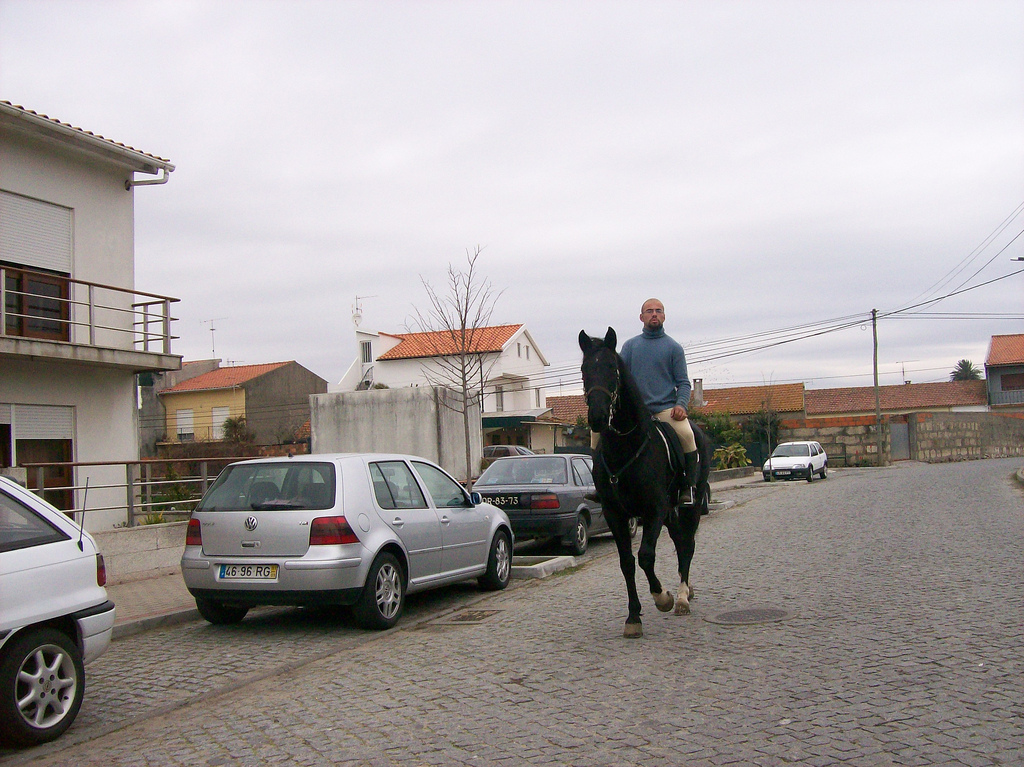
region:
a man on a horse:
[546, 241, 758, 671]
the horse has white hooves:
[591, 572, 721, 665]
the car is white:
[748, 432, 837, 506]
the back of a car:
[15, 443, 130, 763]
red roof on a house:
[360, 315, 544, 364]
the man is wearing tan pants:
[568, 268, 717, 645]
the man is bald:
[635, 285, 689, 336]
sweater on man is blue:
[622, 329, 702, 422]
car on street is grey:
[175, 449, 511, 614]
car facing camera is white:
[769, 434, 834, 489]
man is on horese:
[564, 295, 760, 646]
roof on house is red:
[374, 319, 558, 368]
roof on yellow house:
[194, 360, 296, 399]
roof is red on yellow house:
[192, 349, 291, 422]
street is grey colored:
[782, 494, 1010, 741]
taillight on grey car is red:
[308, 515, 385, 572]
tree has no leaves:
[415, 279, 527, 460]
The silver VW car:
[174, 433, 536, 639]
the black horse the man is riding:
[579, 313, 741, 664]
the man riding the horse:
[617, 288, 735, 507]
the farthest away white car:
[762, 420, 849, 510]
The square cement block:
[308, 379, 498, 507]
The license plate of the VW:
[215, 556, 301, 601]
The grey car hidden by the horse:
[454, 440, 628, 573]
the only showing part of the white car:
[2, 464, 158, 744]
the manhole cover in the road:
[697, 590, 805, 657]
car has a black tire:
[193, 598, 255, 625]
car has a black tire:
[348, 556, 409, 632]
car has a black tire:
[478, 534, 516, 588]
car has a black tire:
[0, 630, 84, 742]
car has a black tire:
[564, 516, 590, 558]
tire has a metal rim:
[10, 646, 80, 732]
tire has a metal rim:
[373, 563, 406, 618]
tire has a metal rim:
[491, 538, 515, 583]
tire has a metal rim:
[576, 523, 589, 547]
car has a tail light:
[310, 512, 356, 545]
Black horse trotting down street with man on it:
[579, 326, 663, 644]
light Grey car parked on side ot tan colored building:
[191, 450, 485, 571]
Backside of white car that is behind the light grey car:
[0, 473, 111, 709]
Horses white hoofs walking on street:
[656, 574, 695, 613]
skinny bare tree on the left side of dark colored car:
[405, 251, 482, 448]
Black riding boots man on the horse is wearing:
[689, 445, 700, 509]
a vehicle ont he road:
[216, 394, 438, 565]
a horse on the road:
[537, 366, 779, 619]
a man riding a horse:
[522, 310, 703, 582]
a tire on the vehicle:
[333, 547, 406, 614]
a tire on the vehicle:
[6, 632, 77, 697]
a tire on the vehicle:
[210, 591, 234, 617]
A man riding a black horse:
[560, 285, 732, 653]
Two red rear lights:
[166, 500, 367, 558]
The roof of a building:
[365, 310, 524, 364]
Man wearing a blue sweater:
[604, 285, 699, 426]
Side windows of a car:
[359, 446, 480, 519]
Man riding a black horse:
[577, 297, 717, 639]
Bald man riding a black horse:
[574, 294, 715, 640]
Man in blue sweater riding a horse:
[575, 296, 715, 642]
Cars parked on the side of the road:
[2, 436, 1018, 760]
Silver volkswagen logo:
[242, 514, 259, 530]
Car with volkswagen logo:
[176, 449, 516, 633]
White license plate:
[211, 556, 279, 582]